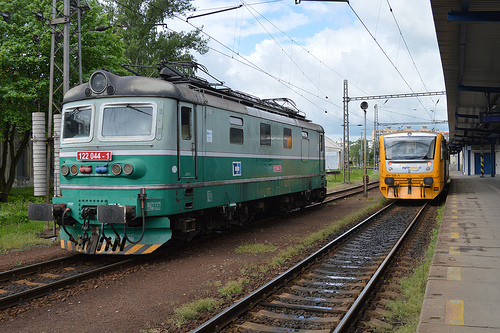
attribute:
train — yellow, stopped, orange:
[379, 126, 451, 204]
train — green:
[56, 70, 328, 254]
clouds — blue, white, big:
[23, 0, 448, 137]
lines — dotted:
[447, 178, 468, 333]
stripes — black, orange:
[56, 238, 159, 256]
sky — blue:
[77, 1, 448, 133]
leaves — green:
[3, 2, 210, 129]